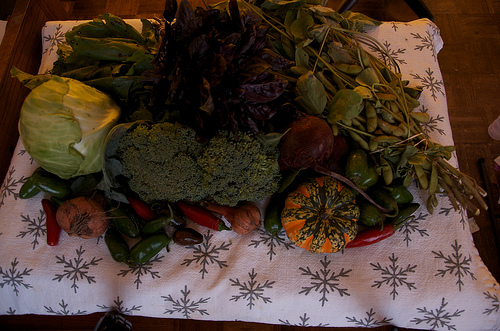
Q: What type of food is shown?
A: Vegetables.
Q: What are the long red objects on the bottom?
A: Peppers.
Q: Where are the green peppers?
A: Beside the red peppers.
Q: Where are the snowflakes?
A: On the cloth.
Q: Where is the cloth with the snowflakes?
A: Under the vegetables.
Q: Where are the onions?
A: Below and to the left of the broccoli.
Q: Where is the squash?
A: Bottom right side.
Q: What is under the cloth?
A: Table.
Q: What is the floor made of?
A: Wood.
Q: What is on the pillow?
A: Vegetables.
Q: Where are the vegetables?
A: On the pillow.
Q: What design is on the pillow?
A: Snowflakes.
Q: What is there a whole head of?
A: Cabbage.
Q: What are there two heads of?
A: Broccoli.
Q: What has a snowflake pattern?
A: Pillow case.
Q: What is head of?
A: Lettuce.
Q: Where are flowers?
A: On pillow.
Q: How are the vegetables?
A: Mixed.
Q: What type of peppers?
A: Red.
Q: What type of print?
A: Snowflake.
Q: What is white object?
A: Pillow.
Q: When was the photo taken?
A: Daytime.